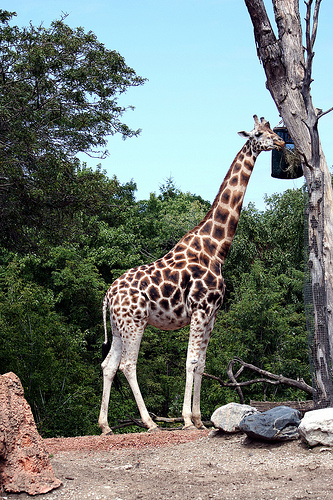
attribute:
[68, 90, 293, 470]
giraffe — tall, large, long, standing, black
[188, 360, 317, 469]
rock — red, large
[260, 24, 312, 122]
tree — large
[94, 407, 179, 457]
dirt — brown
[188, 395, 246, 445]
stone — grey, black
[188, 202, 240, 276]
spots — brown, large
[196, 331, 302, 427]
fence — mesh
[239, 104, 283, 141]
hair — brown